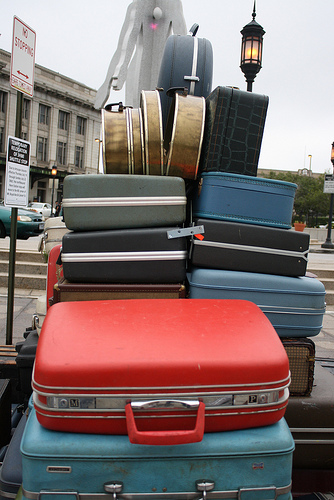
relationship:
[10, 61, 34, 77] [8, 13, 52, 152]
arrow on sign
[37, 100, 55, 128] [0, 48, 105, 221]
window on building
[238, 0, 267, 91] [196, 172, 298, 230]
lamp post on blue suitcase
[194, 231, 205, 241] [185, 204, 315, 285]
sticker on suitcase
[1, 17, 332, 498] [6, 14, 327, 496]
large stack on suitcases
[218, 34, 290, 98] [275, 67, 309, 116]
street lamp on right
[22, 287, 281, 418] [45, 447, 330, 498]
suit case in foreground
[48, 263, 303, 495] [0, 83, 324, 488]
pile of suitcases